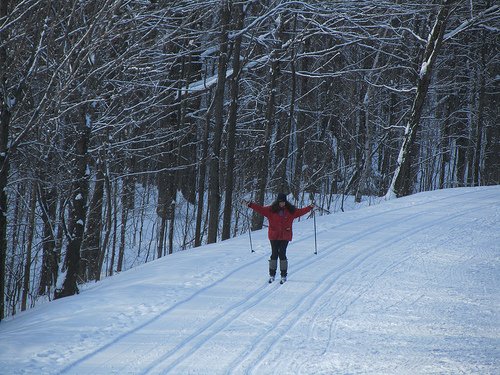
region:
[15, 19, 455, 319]
this is a ski area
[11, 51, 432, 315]
it is cold here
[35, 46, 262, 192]
the trees are bare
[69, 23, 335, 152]
the tree branches are covered in snow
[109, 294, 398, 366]
the ground here is very white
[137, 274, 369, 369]
the street is covered in snow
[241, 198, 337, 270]
this is a skier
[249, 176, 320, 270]
the person is skiing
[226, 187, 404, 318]
the person is holding ski poles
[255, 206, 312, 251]
the person has red jacket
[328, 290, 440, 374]
a ground covered in snow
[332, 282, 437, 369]
ground covered in white snow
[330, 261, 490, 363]
snow covering the ground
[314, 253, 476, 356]
white snow covering the ground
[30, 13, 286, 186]
trees covered in snow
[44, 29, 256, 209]
trees covered in white snow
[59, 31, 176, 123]
snow on the trees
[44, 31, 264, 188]
white snow covering the trees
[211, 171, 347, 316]
a person skiing outside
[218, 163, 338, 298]
a perso skiing on the snow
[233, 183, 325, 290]
person skiing on hill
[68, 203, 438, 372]
ski tracks in snow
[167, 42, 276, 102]
snow covered branches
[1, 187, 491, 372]
snow covered slope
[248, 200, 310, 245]
red winter jacket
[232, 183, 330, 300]
person with arms outstretched on snow covered hill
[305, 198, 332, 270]
ski pole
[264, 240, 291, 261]
black pants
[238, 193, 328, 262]
two ski poles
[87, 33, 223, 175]
bare leafless branches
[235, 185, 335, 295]
skier on the snow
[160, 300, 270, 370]
marks of skis on the snow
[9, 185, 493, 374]
field is covered with snow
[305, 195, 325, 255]
snow pole on left arm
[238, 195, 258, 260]
snow pole on right arm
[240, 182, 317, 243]
woman has long hair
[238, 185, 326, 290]
woman has outstretched arms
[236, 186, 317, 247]
woman has red coat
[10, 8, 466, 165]
snow over brown branches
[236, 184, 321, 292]
woman has black pants